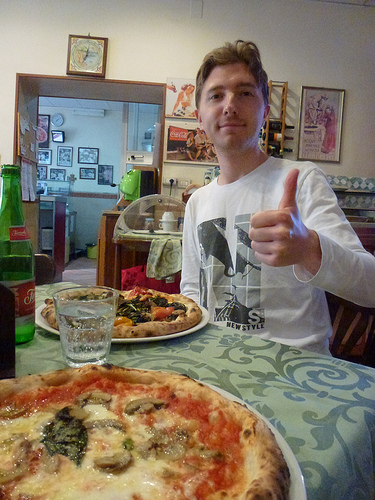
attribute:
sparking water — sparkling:
[51, 283, 120, 368]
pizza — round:
[1, 367, 293, 497]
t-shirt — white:
[179, 156, 374, 366]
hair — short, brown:
[188, 30, 282, 116]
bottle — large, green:
[2, 160, 43, 363]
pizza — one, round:
[38, 352, 223, 497]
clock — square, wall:
[48, 104, 62, 129]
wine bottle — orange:
[263, 131, 295, 142]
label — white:
[272, 130, 282, 140]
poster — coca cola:
[156, 117, 222, 172]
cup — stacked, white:
[156, 209, 180, 221]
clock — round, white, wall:
[50, 111, 64, 126]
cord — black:
[169, 178, 172, 197]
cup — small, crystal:
[50, 286, 121, 366]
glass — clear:
[56, 275, 127, 369]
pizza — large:
[0, 351, 293, 498]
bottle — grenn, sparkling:
[2, 156, 38, 342]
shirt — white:
[179, 155, 373, 356]